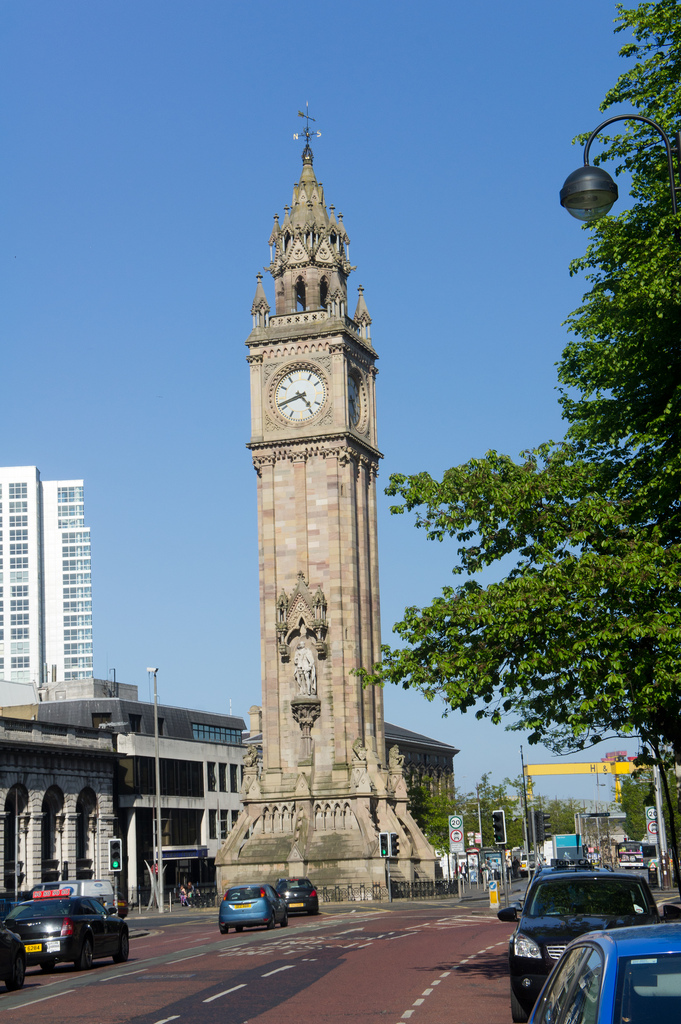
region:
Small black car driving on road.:
[270, 868, 325, 912]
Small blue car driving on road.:
[217, 878, 288, 926]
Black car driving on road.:
[5, 898, 143, 952]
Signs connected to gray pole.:
[446, 811, 465, 897]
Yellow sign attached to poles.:
[515, 748, 640, 783]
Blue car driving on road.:
[538, 913, 680, 1019]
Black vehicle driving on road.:
[509, 860, 648, 986]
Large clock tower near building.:
[232, 334, 403, 891]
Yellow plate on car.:
[21, 939, 49, 952]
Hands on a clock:
[278, 389, 310, 407]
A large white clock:
[276, 365, 323, 420]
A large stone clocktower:
[220, 109, 436, 888]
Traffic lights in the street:
[376, 832, 397, 855]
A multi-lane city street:
[0, 882, 680, 1022]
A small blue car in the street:
[215, 884, 288, 935]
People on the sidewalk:
[176, 878, 196, 907]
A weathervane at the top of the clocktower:
[290, 99, 319, 146]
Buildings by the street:
[1, 692, 462, 922]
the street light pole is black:
[560, 115, 679, 229]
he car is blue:
[218, 880, 288, 930]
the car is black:
[6, 886, 128, 969]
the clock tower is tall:
[215, 98, 440, 905]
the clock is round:
[274, 369, 326, 422]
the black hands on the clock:
[274, 369, 326, 422]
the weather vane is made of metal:
[289, 98, 322, 151]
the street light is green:
[107, 861, 121, 868]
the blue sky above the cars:
[0, 1, 680, 1019]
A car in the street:
[11, 892, 137, 968]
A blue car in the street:
[522, 912, 679, 1019]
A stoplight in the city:
[374, 824, 405, 862]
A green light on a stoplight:
[105, 856, 122, 871]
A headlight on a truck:
[508, 926, 545, 963]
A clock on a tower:
[267, 362, 326, 425]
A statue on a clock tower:
[286, 630, 318, 699]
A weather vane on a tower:
[288, 97, 328, 157]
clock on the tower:
[265, 362, 330, 429]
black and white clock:
[265, 360, 326, 423]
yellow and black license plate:
[25, 937, 41, 954]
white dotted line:
[393, 932, 509, 1022]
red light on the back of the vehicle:
[253, 883, 268, 899]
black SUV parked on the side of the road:
[498, 867, 678, 1021]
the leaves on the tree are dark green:
[347, 2, 678, 757]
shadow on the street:
[408, 943, 510, 986]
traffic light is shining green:
[107, 832, 124, 872]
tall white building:
[1, 461, 98, 699]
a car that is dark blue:
[263, 876, 340, 924]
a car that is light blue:
[213, 881, 298, 937]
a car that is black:
[5, 893, 128, 968]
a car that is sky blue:
[554, 919, 679, 1019]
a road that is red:
[315, 925, 459, 1021]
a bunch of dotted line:
[398, 952, 468, 1022]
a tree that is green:
[419, 788, 510, 852]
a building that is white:
[6, 461, 108, 717]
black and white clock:
[251, 351, 330, 438]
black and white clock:
[339, 360, 368, 443]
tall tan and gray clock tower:
[208, 89, 397, 808]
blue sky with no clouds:
[12, 220, 64, 279]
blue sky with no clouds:
[145, 357, 197, 413]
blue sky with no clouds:
[393, 166, 455, 232]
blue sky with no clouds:
[408, 304, 458, 346]